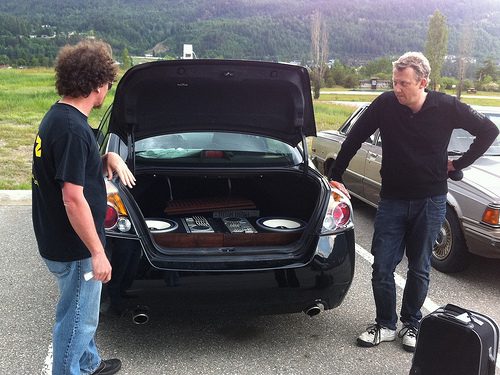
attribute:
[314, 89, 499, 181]
shirt — black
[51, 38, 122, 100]
hair — brown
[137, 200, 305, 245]
speakers — car's,  man's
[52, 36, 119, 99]
curly hair —  brown,  curly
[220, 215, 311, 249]
speaker — big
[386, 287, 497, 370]
suitcase — Black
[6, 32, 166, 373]
man — brown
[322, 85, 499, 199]
dark shirt —  dark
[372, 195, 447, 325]
blue jeans —  dark blue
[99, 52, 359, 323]
black car —  black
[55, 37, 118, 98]
hair — curly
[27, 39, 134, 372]
friend —  man's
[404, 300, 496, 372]
suitcase — black, small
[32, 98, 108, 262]
t-shirt — black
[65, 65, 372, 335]
car — black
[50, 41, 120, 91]
hair — curly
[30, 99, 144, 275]
shirt — black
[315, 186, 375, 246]
taillights — flashy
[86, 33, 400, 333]
car — black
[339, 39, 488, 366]
guy — older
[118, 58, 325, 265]
trunk —  open,  car's